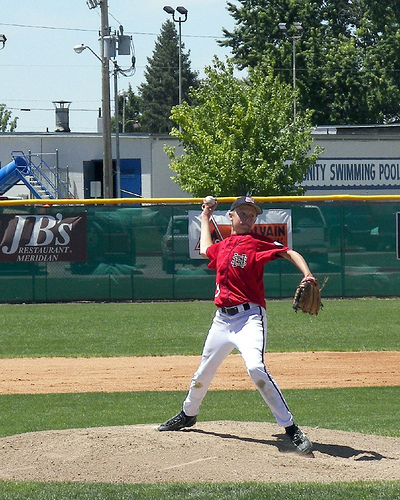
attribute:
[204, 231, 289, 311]
jersey — red 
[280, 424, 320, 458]
cleat — grey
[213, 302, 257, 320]
belt — brown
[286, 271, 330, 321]
glove — tan 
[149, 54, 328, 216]
tree — small , green 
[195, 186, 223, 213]
baseball — white 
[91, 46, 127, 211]
pole — brown 